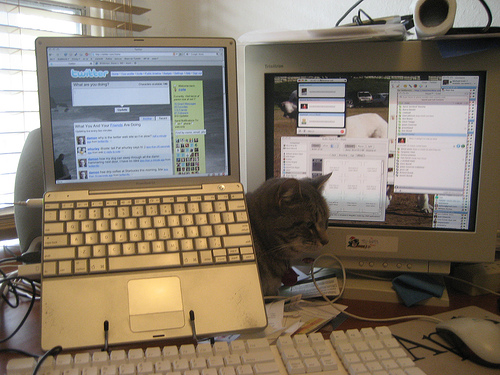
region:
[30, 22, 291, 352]
the sign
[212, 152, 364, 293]
a grey cat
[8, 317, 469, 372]
a white keyboard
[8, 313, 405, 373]
a white keyboard attached to a computer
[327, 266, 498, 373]
a white mouse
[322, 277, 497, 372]
a white mousepad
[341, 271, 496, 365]
a white mouse on a white mouse pad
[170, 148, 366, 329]
a grey cat behind a laptop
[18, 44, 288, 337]
a silver laptop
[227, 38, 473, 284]
a white computer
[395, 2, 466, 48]
a white webcam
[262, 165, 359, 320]
cat on a desk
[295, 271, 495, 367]
white computer mouse and chord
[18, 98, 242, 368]
small white laptop on desk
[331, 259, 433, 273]
five white small knobs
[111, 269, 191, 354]
mouse pad of a laptop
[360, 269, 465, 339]
small blue cloth under computer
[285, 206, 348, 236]
two eyes of a cat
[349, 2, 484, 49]
white head phones on computer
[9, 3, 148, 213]
white shades on a window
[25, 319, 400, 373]
white keyboard on desk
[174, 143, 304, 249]
the cat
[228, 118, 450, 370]
the cat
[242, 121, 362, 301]
the cat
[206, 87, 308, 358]
the cat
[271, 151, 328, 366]
the cat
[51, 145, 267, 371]
the computer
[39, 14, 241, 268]
the computer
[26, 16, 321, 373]
the computer